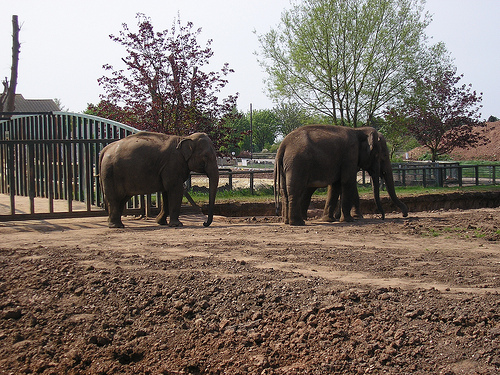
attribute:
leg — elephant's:
[338, 180, 358, 222]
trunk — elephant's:
[201, 166, 222, 231]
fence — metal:
[27, 118, 89, 193]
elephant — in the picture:
[97, 131, 220, 228]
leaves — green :
[257, 1, 436, 146]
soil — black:
[146, 331, 221, 369]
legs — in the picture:
[160, 187, 185, 229]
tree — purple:
[98, 17, 239, 152]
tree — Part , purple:
[249, 0, 454, 161]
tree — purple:
[393, 57, 491, 165]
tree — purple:
[247, 108, 279, 154]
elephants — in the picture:
[84, 129, 419, 233]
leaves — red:
[380, 64, 496, 151]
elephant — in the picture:
[274, 127, 407, 219]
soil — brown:
[424, 129, 494, 164]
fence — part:
[419, 149, 499, 198]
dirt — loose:
[1, 204, 498, 372]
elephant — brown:
[263, 117, 411, 230]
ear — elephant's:
[174, 138, 196, 160]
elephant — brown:
[88, 125, 222, 237]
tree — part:
[98, 40, 233, 150]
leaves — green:
[251, 1, 458, 147]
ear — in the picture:
[176, 137, 196, 162]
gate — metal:
[0, 108, 167, 236]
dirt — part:
[29, 271, 475, 366]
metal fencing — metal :
[2, 112, 180, 224]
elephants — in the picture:
[84, 118, 410, 231]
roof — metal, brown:
[19, 82, 52, 105]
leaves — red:
[154, 7, 219, 84]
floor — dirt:
[289, 258, 374, 336]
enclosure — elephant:
[60, 141, 475, 342]